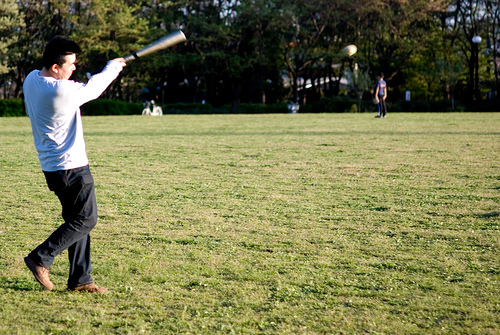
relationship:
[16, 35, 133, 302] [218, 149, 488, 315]
man on grass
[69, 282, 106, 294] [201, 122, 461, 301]
shoe on grass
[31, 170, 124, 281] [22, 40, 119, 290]
pants on man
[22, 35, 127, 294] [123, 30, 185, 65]
man holding silver bat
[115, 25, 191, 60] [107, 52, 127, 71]
bat in hand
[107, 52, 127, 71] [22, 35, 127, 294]
hand of man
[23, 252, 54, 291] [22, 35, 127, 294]
shoe on man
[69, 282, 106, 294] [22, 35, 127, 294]
shoe on man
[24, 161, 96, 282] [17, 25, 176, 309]
pants on man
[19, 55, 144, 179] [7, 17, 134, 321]
shirt on man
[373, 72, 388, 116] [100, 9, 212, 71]
pitcher holding bat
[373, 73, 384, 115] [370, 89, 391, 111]
man holding glove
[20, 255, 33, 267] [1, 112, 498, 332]
heel on ground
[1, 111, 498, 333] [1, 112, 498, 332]
green grass on ground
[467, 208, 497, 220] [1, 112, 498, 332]
shadow on ground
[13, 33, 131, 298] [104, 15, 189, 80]
person holding bat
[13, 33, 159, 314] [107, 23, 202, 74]
person swinging a bat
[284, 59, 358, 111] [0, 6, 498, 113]
white house behind tree line